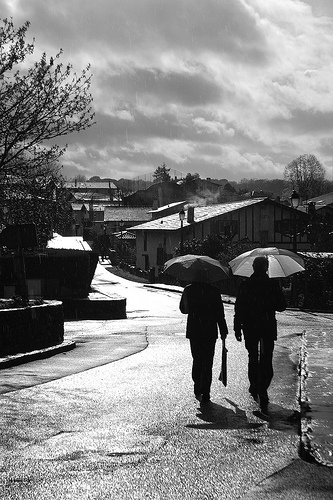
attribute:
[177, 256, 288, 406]
people — holding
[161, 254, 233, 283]
umbrella — black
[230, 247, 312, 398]
person umbrella — black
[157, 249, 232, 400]
person umbrella — black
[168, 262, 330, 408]
people — carrying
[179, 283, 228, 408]
person — holding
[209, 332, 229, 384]
briefcase — black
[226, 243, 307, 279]
umbrella — opened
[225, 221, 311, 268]
umbrella — black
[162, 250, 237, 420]
people — walking